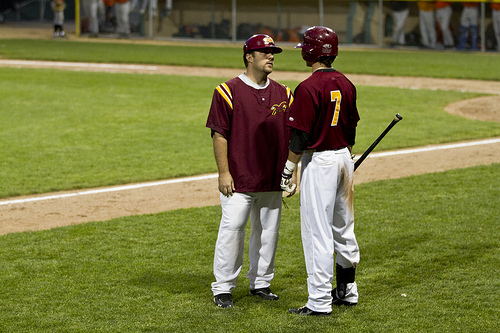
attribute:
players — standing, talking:
[224, 3, 331, 191]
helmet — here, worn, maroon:
[314, 30, 340, 41]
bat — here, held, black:
[371, 129, 398, 162]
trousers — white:
[308, 203, 329, 274]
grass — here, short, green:
[105, 50, 115, 54]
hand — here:
[217, 171, 238, 197]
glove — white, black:
[276, 176, 295, 193]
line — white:
[463, 141, 470, 144]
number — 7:
[320, 87, 347, 126]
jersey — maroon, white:
[249, 113, 250, 123]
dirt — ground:
[415, 80, 421, 81]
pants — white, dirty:
[219, 231, 292, 271]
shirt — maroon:
[319, 79, 327, 83]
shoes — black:
[252, 290, 269, 298]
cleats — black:
[335, 269, 352, 286]